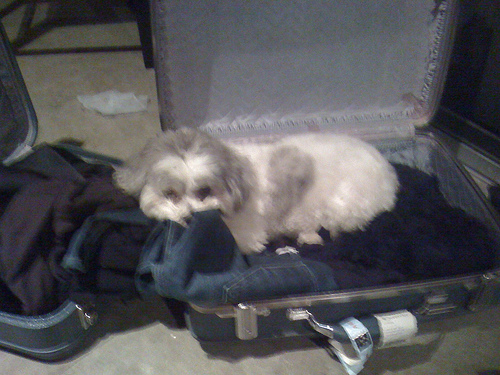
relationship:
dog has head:
[114, 128, 401, 253] [110, 128, 255, 228]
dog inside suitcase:
[114, 128, 401, 253] [151, 0, 498, 344]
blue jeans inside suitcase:
[134, 211, 337, 305] [151, 0, 498, 344]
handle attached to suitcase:
[288, 295, 460, 342] [151, 0, 498, 344]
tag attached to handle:
[330, 316, 372, 373] [288, 295, 460, 342]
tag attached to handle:
[371, 309, 417, 351] [288, 295, 460, 342]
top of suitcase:
[148, 1, 458, 140] [151, 0, 498, 344]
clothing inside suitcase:
[298, 160, 494, 289] [151, 0, 498, 344]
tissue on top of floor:
[76, 87, 150, 115] [2, 2, 499, 374]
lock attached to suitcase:
[234, 301, 260, 340] [151, 0, 498, 344]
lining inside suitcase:
[382, 144, 488, 221] [151, 0, 498, 344]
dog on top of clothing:
[114, 128, 401, 253] [298, 160, 494, 289]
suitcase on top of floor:
[151, 0, 498, 344] [2, 2, 499, 374]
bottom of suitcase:
[164, 129, 499, 347] [151, 0, 498, 344]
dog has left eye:
[114, 128, 401, 253] [197, 186, 210, 197]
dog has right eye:
[114, 128, 401, 253] [164, 189, 177, 199]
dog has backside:
[114, 128, 401, 253] [349, 136, 399, 209]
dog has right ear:
[114, 128, 401, 253] [213, 140, 258, 216]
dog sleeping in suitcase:
[114, 128, 401, 253] [151, 0, 498, 344]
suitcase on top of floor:
[1, 25, 153, 363] [2, 2, 499, 374]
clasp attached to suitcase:
[76, 299, 101, 331] [1, 25, 153, 363]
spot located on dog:
[263, 146, 315, 219] [114, 128, 401, 253]